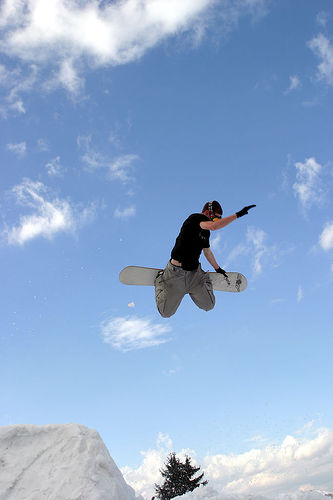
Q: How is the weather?
A: It is cloudy.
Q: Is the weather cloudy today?
A: Yes, it is cloudy.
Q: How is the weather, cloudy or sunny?
A: It is cloudy.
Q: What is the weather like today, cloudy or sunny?
A: It is cloudy.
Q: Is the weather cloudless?
A: No, it is cloudy.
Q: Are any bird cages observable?
A: No, there are no bird cages.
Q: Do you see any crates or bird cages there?
A: No, there are no bird cages or crates.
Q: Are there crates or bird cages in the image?
A: No, there are no bird cages or crates.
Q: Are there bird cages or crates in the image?
A: No, there are no bird cages or crates.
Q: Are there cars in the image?
A: No, there are no cars.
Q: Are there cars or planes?
A: No, there are no cars or planes.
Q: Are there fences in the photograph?
A: No, there are no fences.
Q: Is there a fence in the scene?
A: No, there are no fences.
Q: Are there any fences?
A: No, there are no fences.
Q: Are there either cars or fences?
A: No, there are no fences or cars.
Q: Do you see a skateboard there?
A: No, there are no skateboards.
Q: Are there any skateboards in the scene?
A: No, there are no skateboards.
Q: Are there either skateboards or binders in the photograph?
A: No, there are no skateboards or binders.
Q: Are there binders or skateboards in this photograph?
A: No, there are no skateboards or binders.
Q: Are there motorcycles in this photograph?
A: No, there are no motorcycles.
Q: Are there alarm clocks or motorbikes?
A: No, there are no motorbikes or alarm clocks.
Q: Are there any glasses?
A: No, there are no glasses.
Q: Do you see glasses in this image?
A: No, there are no glasses.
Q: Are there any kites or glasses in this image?
A: No, there are no glasses or kites.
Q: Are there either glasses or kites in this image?
A: No, there are no glasses or kites.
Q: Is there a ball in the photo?
A: No, there are no balls.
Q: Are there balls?
A: No, there are no balls.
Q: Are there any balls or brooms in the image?
A: No, there are no balls or brooms.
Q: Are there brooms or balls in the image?
A: No, there are no balls or brooms.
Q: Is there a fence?
A: No, there are no fences.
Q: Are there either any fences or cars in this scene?
A: No, there are no fences or cars.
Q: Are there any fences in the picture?
A: No, there are no fences.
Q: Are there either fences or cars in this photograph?
A: No, there are no fences or cars.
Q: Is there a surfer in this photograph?
A: No, there are no surfers.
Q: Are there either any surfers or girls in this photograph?
A: No, there are no surfers or girls.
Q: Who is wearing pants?
A: The man is wearing pants.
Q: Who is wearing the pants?
A: The man is wearing pants.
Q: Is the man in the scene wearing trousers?
A: Yes, the man is wearing trousers.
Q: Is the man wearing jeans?
A: No, the man is wearing trousers.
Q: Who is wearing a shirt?
A: The man is wearing a shirt.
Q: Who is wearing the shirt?
A: The man is wearing a shirt.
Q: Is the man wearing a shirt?
A: Yes, the man is wearing a shirt.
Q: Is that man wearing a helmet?
A: No, the man is wearing a shirt.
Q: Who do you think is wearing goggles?
A: The man is wearing goggles.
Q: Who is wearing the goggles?
A: The man is wearing goggles.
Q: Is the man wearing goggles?
A: Yes, the man is wearing goggles.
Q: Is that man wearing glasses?
A: No, the man is wearing goggles.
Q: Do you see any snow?
A: Yes, there is snow.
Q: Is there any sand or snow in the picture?
A: Yes, there is snow.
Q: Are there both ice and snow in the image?
A: No, there is snow but no ice.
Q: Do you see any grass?
A: No, there is no grass.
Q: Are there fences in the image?
A: No, there are no fences.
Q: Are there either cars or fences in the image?
A: No, there are no fences or cars.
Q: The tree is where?
A: The tree is in the snow.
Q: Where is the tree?
A: The tree is in the snow.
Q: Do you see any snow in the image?
A: Yes, there is snow.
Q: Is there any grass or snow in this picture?
A: Yes, there is snow.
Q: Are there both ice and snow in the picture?
A: No, there is snow but no ice.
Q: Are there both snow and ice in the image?
A: No, there is snow but no ice.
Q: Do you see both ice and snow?
A: No, there is snow but no ice.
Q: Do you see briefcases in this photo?
A: No, there are no briefcases.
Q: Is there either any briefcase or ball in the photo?
A: No, there are no briefcases or balls.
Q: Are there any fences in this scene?
A: No, there are no fences.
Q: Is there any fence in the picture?
A: No, there are no fences.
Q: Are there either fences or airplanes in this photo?
A: No, there are no fences or airplanes.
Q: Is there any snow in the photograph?
A: Yes, there is snow.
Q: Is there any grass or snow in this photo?
A: Yes, there is snow.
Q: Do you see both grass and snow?
A: No, there is snow but no grass.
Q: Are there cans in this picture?
A: No, there are no cans.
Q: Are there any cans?
A: No, there are no cans.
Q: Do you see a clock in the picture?
A: No, there are no clocks.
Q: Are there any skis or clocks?
A: No, there are no clocks or skis.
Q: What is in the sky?
A: The clouds are in the sky.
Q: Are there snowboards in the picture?
A: Yes, there is a snowboard.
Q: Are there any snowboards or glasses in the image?
A: Yes, there is a snowboard.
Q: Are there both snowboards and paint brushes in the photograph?
A: No, there is a snowboard but no paint brushes.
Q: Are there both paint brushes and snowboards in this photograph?
A: No, there is a snowboard but no paint brushes.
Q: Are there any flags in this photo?
A: No, there are no flags.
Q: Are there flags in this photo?
A: No, there are no flags.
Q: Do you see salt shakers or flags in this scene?
A: No, there are no flags or salt shakers.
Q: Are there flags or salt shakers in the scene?
A: No, there are no flags or salt shakers.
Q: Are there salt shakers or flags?
A: No, there are no flags or salt shakers.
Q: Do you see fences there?
A: No, there are no fences.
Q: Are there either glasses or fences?
A: No, there are no fences or glasses.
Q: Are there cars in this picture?
A: No, there are no cars.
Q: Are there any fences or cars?
A: No, there are no cars or fences.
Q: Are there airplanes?
A: No, there are no airplanes.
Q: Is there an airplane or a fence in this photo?
A: No, there are no airplanes or fences.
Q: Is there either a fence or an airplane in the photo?
A: No, there are no airplanes or fences.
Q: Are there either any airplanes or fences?
A: No, there are no airplanes or fences.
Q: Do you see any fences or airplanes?
A: No, there are no airplanes or fences.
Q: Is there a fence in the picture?
A: No, there are no fences.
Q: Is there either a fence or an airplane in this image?
A: No, there are no fences or airplanes.